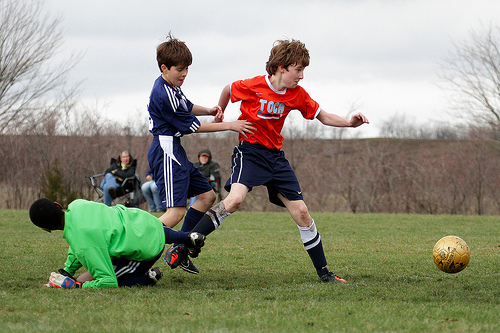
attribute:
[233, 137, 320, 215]
shorts — white, black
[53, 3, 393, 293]
boys — playing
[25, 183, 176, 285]
shirt — green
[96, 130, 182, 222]
man — sitting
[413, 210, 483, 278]
ball — gold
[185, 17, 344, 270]
boy — trying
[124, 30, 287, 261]
boy — trying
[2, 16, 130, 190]
trees — leafless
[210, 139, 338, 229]
shorts — blue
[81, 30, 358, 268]
kids — playing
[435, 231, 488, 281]
ball — golden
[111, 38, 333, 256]
boy — jumping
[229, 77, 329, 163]
jersey — red